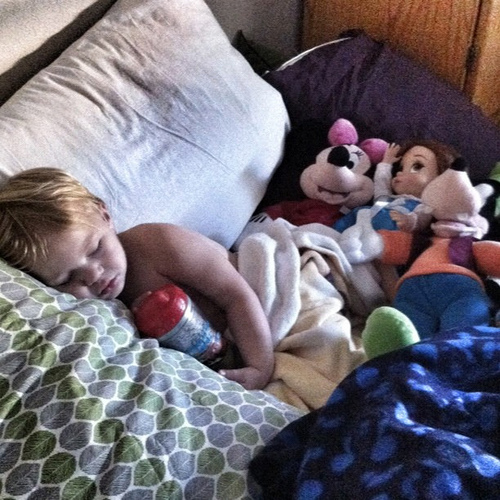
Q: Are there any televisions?
A: No, there are no televisions.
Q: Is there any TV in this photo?
A: No, there are no televisions.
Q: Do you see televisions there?
A: No, there are no televisions.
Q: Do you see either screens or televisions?
A: No, there are no televisions or screens.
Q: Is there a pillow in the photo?
A: Yes, there is a pillow.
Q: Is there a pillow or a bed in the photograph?
A: Yes, there is a pillow.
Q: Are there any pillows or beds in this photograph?
A: Yes, there is a pillow.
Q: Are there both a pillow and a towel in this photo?
A: No, there is a pillow but no towels.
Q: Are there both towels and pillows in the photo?
A: No, there is a pillow but no towels.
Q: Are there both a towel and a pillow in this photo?
A: No, there is a pillow but no towels.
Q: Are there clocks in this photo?
A: No, there are no clocks.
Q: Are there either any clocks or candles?
A: No, there are no clocks or candles.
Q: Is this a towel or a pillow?
A: This is a pillow.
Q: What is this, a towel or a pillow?
A: This is a pillow.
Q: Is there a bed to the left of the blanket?
A: No, there is a pillow to the left of the blanket.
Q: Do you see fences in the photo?
A: No, there are no fences.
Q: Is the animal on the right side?
A: Yes, the animal is on the right of the image.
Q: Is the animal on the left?
A: No, the animal is on the right of the image.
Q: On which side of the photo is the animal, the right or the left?
A: The animal is on the right of the image.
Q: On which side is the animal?
A: The animal is on the right of the image.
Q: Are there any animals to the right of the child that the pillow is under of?
A: Yes, there is an animal to the right of the child.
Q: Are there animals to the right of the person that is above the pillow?
A: Yes, there is an animal to the right of the child.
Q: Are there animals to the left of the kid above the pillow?
A: No, the animal is to the right of the kid.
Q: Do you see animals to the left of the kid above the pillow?
A: No, the animal is to the right of the kid.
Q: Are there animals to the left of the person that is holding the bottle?
A: No, the animal is to the right of the kid.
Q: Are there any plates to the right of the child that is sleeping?
A: No, there is an animal to the right of the kid.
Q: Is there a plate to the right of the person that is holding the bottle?
A: No, there is an animal to the right of the kid.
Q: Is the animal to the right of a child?
A: Yes, the animal is to the right of a child.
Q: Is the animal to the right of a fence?
A: No, the animal is to the right of a child.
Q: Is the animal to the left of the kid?
A: No, the animal is to the right of the kid.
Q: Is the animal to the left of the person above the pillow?
A: No, the animal is to the right of the kid.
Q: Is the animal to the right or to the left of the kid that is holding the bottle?
A: The animal is to the right of the child.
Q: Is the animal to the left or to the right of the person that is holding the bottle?
A: The animal is to the right of the child.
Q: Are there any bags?
A: No, there are no bags.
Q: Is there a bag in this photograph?
A: No, there are no bags.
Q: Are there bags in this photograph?
A: No, there are no bags.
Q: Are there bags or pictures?
A: No, there are no bags or pictures.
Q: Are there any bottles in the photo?
A: Yes, there is a bottle.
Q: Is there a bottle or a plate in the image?
A: Yes, there is a bottle.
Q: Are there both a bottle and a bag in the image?
A: No, there is a bottle but no bags.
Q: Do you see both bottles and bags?
A: No, there is a bottle but no bags.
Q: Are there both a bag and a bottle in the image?
A: No, there is a bottle but no bags.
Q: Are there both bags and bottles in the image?
A: No, there is a bottle but no bags.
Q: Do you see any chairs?
A: No, there are no chairs.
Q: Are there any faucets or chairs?
A: No, there are no chairs or faucets.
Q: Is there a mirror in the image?
A: No, there are no mirrors.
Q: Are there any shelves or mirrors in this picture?
A: No, there are no mirrors or shelves.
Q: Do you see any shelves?
A: No, there are no shelves.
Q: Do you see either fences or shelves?
A: No, there are no shelves or fences.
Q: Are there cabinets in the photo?
A: Yes, there is a cabinet.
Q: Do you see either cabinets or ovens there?
A: Yes, there is a cabinet.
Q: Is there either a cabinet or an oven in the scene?
A: Yes, there is a cabinet.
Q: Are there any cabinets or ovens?
A: Yes, there is a cabinet.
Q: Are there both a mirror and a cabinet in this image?
A: No, there is a cabinet but no mirrors.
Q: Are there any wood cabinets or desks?
A: Yes, there is a wood cabinet.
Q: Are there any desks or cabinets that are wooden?
A: Yes, the cabinet is wooden.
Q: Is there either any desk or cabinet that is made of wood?
A: Yes, the cabinet is made of wood.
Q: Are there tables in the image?
A: No, there are no tables.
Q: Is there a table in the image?
A: No, there are no tables.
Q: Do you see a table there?
A: No, there are no tables.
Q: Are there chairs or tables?
A: No, there are no tables or chairs.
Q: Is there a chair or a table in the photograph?
A: No, there are no tables or chairs.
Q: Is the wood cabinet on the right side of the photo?
A: Yes, the cabinet is on the right of the image.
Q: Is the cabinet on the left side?
A: No, the cabinet is on the right of the image.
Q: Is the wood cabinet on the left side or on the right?
A: The cabinet is on the right of the image.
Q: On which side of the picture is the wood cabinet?
A: The cabinet is on the right of the image.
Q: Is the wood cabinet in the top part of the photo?
A: Yes, the cabinet is in the top of the image.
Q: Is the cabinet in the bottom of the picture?
A: No, the cabinet is in the top of the image.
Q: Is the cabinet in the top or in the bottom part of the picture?
A: The cabinet is in the top of the image.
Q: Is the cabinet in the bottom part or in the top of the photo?
A: The cabinet is in the top of the image.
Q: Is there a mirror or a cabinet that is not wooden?
A: No, there is a cabinet but it is wooden.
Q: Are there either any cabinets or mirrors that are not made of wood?
A: No, there is a cabinet but it is made of wood.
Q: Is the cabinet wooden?
A: Yes, the cabinet is wooden.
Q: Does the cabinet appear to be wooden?
A: Yes, the cabinet is wooden.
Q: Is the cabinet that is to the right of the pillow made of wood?
A: Yes, the cabinet is made of wood.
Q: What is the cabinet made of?
A: The cabinet is made of wood.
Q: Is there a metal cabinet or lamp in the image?
A: No, there is a cabinet but it is wooden.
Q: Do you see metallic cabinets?
A: No, there is a cabinet but it is wooden.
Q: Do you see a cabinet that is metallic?
A: No, there is a cabinet but it is wooden.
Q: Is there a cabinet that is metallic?
A: No, there is a cabinet but it is wooden.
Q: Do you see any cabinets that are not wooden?
A: No, there is a cabinet but it is wooden.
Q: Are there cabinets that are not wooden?
A: No, there is a cabinet but it is wooden.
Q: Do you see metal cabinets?
A: No, there is a cabinet but it is made of wood.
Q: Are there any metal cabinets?
A: No, there is a cabinet but it is made of wood.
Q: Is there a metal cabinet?
A: No, there is a cabinet but it is made of wood.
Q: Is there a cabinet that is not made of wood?
A: No, there is a cabinet but it is made of wood.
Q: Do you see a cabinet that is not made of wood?
A: No, there is a cabinet but it is made of wood.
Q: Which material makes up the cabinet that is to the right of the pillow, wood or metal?
A: The cabinet is made of wood.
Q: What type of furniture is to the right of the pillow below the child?
A: The piece of furniture is a cabinet.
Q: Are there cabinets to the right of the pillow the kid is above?
A: Yes, there is a cabinet to the right of the pillow.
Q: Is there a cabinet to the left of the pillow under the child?
A: No, the cabinet is to the right of the pillow.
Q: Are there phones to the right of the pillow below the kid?
A: No, there is a cabinet to the right of the pillow.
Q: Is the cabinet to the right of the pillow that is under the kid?
A: Yes, the cabinet is to the right of the pillow.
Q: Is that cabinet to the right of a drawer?
A: No, the cabinet is to the right of the pillow.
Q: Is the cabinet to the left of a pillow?
A: No, the cabinet is to the right of a pillow.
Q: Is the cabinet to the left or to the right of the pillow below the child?
A: The cabinet is to the right of the pillow.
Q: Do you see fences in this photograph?
A: No, there are no fences.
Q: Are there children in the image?
A: Yes, there is a child.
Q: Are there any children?
A: Yes, there is a child.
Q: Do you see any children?
A: Yes, there is a child.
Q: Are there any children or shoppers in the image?
A: Yes, there is a child.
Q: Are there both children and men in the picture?
A: No, there is a child but no men.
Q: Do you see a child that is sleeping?
A: Yes, there is a child that is sleeping.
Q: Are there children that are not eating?
A: Yes, there is a child that is sleeping.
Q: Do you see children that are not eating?
A: Yes, there is a child that is sleeping .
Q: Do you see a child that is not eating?
A: Yes, there is a child that is sleeping .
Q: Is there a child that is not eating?
A: Yes, there is a child that is sleeping.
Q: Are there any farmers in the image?
A: No, there are no farmers.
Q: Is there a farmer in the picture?
A: No, there are no farmers.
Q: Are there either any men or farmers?
A: No, there are no farmers or men.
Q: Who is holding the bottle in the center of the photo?
A: The child is holding the bottle.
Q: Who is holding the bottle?
A: The child is holding the bottle.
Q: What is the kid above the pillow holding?
A: The child is holding the bottle.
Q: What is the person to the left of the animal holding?
A: The child is holding the bottle.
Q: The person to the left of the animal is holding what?
A: The child is holding the bottle.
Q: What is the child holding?
A: The child is holding the bottle.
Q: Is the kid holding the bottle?
A: Yes, the kid is holding the bottle.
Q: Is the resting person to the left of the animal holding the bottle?
A: Yes, the kid is holding the bottle.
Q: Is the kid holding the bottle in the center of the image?
A: Yes, the kid is holding the bottle.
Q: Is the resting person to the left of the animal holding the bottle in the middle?
A: Yes, the kid is holding the bottle.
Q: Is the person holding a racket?
A: No, the child is holding the bottle.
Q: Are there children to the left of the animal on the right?
A: Yes, there is a child to the left of the animal.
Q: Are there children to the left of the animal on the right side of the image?
A: Yes, there is a child to the left of the animal.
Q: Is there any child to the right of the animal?
A: No, the child is to the left of the animal.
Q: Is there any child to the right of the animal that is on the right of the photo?
A: No, the child is to the left of the animal.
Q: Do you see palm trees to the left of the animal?
A: No, there is a child to the left of the animal.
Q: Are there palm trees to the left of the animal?
A: No, there is a child to the left of the animal.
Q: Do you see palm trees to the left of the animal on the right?
A: No, there is a child to the left of the animal.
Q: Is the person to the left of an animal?
A: Yes, the child is to the left of an animal.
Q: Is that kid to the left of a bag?
A: No, the kid is to the left of an animal.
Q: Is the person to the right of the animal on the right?
A: No, the child is to the left of the animal.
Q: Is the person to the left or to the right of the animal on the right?
A: The child is to the left of the animal.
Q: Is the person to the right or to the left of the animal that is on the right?
A: The child is to the left of the animal.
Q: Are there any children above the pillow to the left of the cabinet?
A: Yes, there is a child above the pillow.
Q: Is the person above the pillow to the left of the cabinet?
A: Yes, the child is above the pillow.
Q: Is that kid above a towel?
A: No, the kid is above the pillow.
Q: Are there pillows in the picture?
A: Yes, there is a pillow.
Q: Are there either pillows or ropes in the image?
A: Yes, there is a pillow.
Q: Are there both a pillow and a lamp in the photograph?
A: No, there is a pillow but no lamps.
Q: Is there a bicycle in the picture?
A: No, there are no bicycles.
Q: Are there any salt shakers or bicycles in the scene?
A: No, there are no bicycles or salt shakers.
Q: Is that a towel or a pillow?
A: That is a pillow.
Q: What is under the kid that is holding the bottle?
A: The pillow is under the child.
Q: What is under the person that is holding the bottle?
A: The pillow is under the child.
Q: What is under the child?
A: The pillow is under the child.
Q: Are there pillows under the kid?
A: Yes, there is a pillow under the kid.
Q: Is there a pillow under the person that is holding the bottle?
A: Yes, there is a pillow under the kid.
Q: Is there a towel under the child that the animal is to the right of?
A: No, there is a pillow under the kid.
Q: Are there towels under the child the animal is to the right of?
A: No, there is a pillow under the kid.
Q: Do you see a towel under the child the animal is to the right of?
A: No, there is a pillow under the kid.